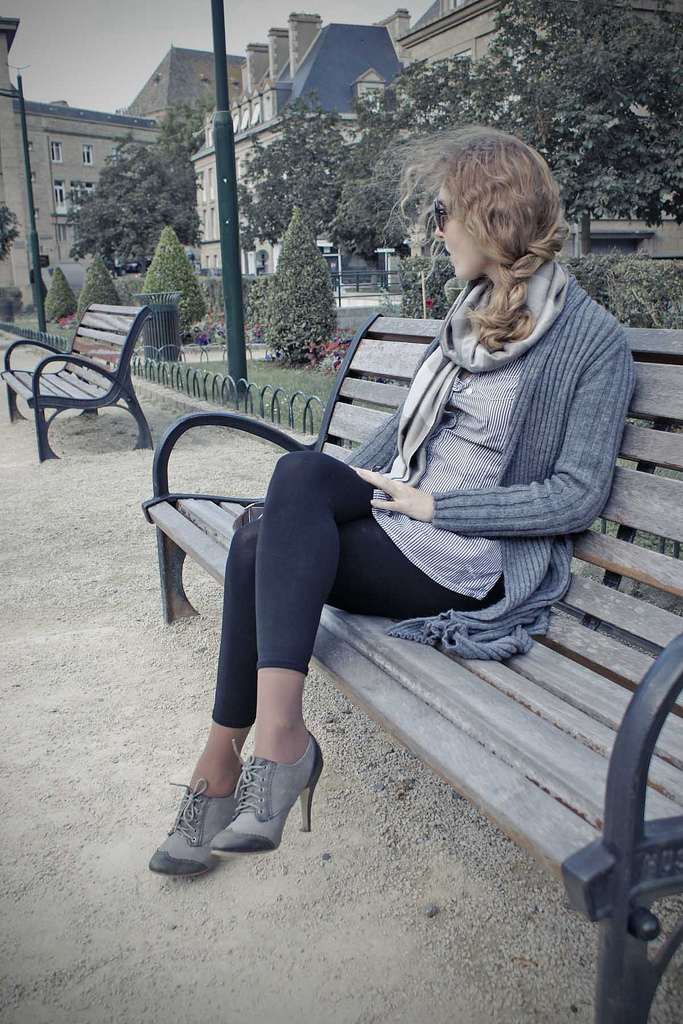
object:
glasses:
[434, 198, 448, 230]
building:
[379, 0, 683, 255]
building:
[189, 19, 408, 279]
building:
[0, 8, 173, 301]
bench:
[139, 315, 683, 1024]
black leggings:
[211, 451, 497, 731]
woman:
[148, 124, 635, 879]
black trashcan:
[134, 290, 185, 362]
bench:
[0, 302, 156, 464]